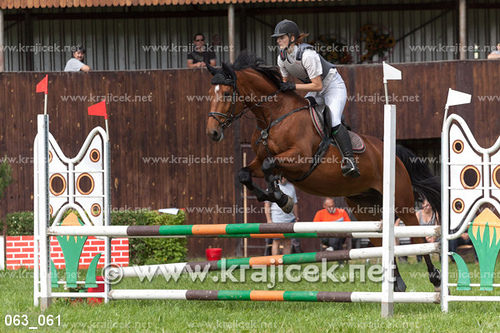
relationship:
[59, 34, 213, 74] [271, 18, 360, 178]
people watching woman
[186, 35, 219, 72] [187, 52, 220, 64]
man wears black shirt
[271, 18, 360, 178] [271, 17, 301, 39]
woman wears a helmet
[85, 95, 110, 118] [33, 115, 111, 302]
flag on gate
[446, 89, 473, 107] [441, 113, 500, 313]
flag on a gate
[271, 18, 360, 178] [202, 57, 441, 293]
woman an a horse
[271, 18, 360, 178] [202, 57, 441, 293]
woman on a horse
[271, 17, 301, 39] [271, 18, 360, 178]
helmet on a woman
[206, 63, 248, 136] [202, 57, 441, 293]
head of a horse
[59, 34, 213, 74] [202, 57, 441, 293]
people watching horse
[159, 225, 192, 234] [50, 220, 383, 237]
green on stick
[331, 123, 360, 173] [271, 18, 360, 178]
boots on woman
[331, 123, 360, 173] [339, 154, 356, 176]
boot in a stirrup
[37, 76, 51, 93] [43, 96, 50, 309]
flag on a pole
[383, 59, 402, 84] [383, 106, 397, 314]
flag on a pole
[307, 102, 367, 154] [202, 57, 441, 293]
saddle on a horse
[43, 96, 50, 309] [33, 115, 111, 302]
pole on a gate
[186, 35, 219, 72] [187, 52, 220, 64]
man in black shirt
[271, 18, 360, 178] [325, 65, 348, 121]
woman wears pants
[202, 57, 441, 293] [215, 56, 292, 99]
horse has black mane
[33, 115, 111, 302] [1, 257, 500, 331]
gate set in grass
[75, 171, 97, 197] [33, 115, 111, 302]
circle in gate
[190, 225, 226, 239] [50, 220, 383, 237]
orange on stick